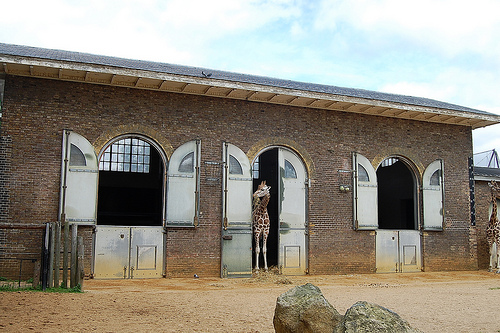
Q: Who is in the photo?
A: No one.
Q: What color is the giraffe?
A: Spotted brown.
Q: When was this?
A: Daytime.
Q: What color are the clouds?
A: White.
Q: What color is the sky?
A: Blue.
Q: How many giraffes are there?
A: One.